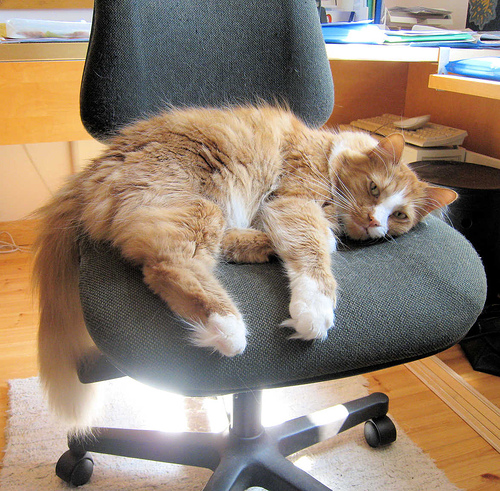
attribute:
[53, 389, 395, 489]
base — black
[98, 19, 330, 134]
fabric — woven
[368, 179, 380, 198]
eye — open, yellow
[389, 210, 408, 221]
eye — open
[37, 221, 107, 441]
tail — furry, bushy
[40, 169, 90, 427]
tail — very fluffy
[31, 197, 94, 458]
fluffy tail — hanging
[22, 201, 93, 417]
tail — cat's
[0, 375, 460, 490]
rug — white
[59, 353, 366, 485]
sunlight — very bright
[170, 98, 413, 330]
cat — orange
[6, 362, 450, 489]
rug — white, area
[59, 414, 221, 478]
caster — black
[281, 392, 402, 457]
caster — black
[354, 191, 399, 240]
nose — pink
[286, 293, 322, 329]
fur — white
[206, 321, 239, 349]
fur — white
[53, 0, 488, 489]
office chair — gray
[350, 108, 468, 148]
keyboard — computer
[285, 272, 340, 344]
cat paws — white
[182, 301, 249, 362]
cat paws — white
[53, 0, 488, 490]
chair — revolving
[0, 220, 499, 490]
flooring — hard wood